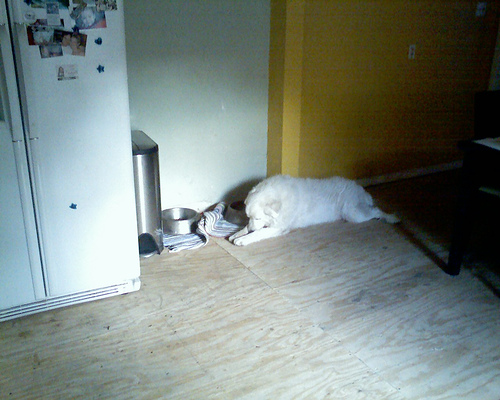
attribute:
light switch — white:
[475, 1, 489, 21]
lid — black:
[130, 129, 156, 155]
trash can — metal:
[132, 128, 161, 259]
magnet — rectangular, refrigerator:
[48, 56, 91, 94]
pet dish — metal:
[157, 197, 204, 243]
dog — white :
[222, 174, 402, 244]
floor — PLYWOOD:
[3, 176, 498, 399]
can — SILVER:
[130, 125, 168, 255]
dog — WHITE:
[221, 171, 399, 251]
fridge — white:
[3, 2, 145, 328]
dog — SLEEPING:
[222, 169, 397, 243]